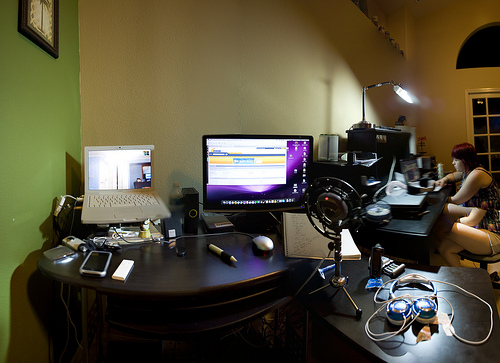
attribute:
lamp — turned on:
[357, 80, 419, 130]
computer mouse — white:
[253, 234, 275, 253]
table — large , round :
[35, 211, 292, 361]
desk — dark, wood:
[24, 222, 496, 358]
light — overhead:
[358, 80, 415, 126]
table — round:
[40, 234, 295, 305]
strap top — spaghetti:
[454, 165, 499, 237]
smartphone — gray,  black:
[76, 246, 116, 281]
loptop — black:
[395, 155, 440, 191]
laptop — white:
[78, 144, 170, 224]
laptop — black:
[401, 153, 442, 200]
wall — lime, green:
[2, 0, 79, 362]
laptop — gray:
[80, 140, 177, 231]